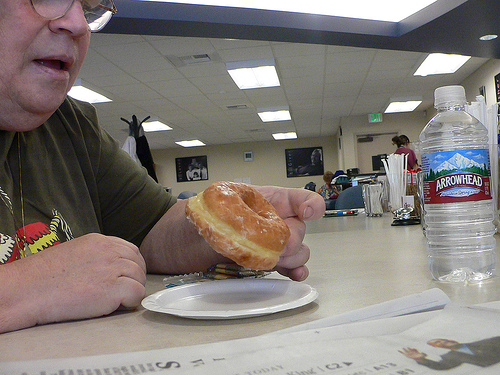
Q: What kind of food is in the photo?
A: Donut.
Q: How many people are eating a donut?
A: One.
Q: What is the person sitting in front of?
A: Table.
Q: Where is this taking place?
A: In a cafeteria.